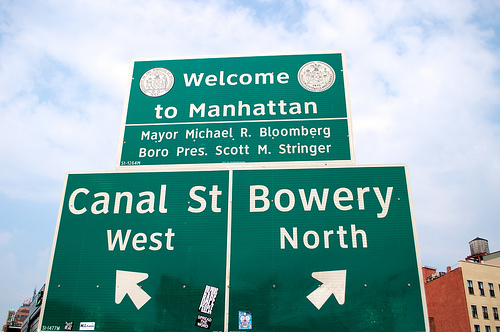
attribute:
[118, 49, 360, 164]
sign — green, above, welcoming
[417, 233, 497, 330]
building — brick